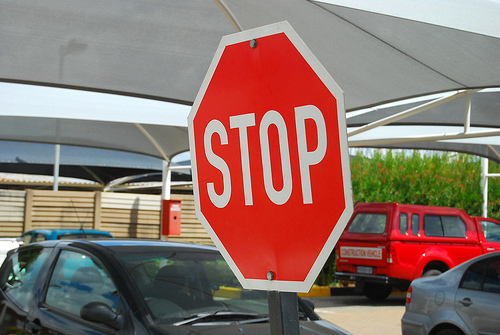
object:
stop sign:
[187, 20, 355, 292]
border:
[185, 21, 353, 294]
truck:
[334, 201, 499, 301]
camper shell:
[341, 201, 478, 242]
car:
[0, 238, 354, 335]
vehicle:
[15, 226, 112, 243]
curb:
[213, 287, 406, 297]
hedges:
[348, 146, 500, 220]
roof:
[1, 0, 500, 115]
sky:
[0, 0, 500, 165]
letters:
[202, 120, 233, 211]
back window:
[346, 210, 386, 234]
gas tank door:
[433, 290, 446, 306]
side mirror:
[78, 299, 120, 324]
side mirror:
[299, 297, 316, 315]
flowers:
[381, 179, 387, 183]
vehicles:
[400, 250, 500, 335]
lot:
[0, 0, 500, 335]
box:
[161, 198, 183, 235]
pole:
[160, 158, 173, 241]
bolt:
[247, 38, 257, 49]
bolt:
[265, 271, 276, 281]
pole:
[265, 290, 302, 334]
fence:
[0, 188, 217, 249]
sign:
[338, 245, 383, 261]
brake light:
[405, 287, 413, 304]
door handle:
[457, 301, 473, 305]